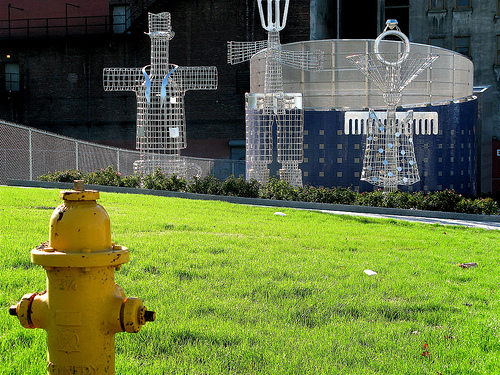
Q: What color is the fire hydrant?
A: Yellow.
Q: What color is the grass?
A: Green.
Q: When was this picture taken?
A: Daytime.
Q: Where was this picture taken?
A: In a park.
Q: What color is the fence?
A: White.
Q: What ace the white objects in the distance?
A: Sculptures.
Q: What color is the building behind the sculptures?
A: Blue.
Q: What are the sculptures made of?
A: Wire mesh.